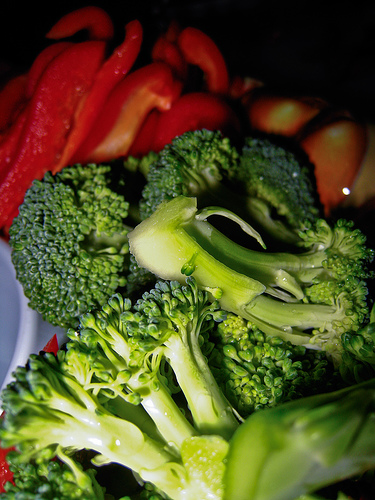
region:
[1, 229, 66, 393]
rim of blue plate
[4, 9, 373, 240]
pile of sliced red bell peppers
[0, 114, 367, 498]
pile of cut broccoli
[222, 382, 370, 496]
blurred edge of broccoli stem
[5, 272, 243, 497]
piece of green broccoli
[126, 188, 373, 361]
cutting of broccoli on top of rest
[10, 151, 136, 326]
crown of broccoli behind rest of pieces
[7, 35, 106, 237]
front most slice of red bell pepper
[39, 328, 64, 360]
shard of something red underneath broccoli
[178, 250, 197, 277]
flower from broccoli floret on stem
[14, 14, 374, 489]
photograph of food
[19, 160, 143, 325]
green broccoli head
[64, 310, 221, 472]
light shining on broccoli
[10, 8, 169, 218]
red peppers cut into long slices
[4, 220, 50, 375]
white plate under vegetables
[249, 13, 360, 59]
background completely dark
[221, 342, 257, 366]
little bulbs on broccoli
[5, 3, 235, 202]
sweet red peppers cut into slices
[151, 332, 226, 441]
green stem of broccoli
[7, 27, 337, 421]
vegetables on a white plate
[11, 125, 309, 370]
cut pieces of raw broccoli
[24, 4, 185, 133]
sliced red bell peppers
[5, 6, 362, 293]
raw crudete on a platter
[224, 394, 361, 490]
close up stalk of broccoli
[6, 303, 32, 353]
part of a white serving dish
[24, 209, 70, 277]
top piece of broccoli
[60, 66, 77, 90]
bright red bell pepper slice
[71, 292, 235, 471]
cut pieces of broccoli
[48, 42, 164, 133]
pepper slices on a plate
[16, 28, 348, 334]
cut pieces of raw vegetables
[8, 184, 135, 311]
PIECE OF GREEN BROCCOLI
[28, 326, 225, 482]
PIECE OF GREEN BROCCOLI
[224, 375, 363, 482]
PIECE OF GREEN BROCCOLI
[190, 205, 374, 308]
PIECE OF GREEN BROCCOLI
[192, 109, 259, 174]
PIECE OF GREEN BROCCOLI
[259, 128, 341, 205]
PIECE OF GREEN BROCCOLI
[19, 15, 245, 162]
RED PEPPERS IN BACKGROUND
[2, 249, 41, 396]
EDGE OF WHITE BOWL ON LEFT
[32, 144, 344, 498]
LARGE BUNCH OF FRESH BROCCOLI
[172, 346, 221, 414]
LIGHT GREEN BROCCOLI STEM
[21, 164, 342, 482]
close up picture of vegetables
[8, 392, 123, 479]
broccoli floret connected to bunch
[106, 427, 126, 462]
drop of moisture on floret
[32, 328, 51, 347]
tip of red pepper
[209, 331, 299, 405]
part of broccoli floret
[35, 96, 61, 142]
stem of red pepper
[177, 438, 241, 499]
moist area in broccoli bunch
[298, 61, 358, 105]
dark area behind vegetables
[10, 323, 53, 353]
edge of white bowl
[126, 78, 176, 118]
curve of red pepper